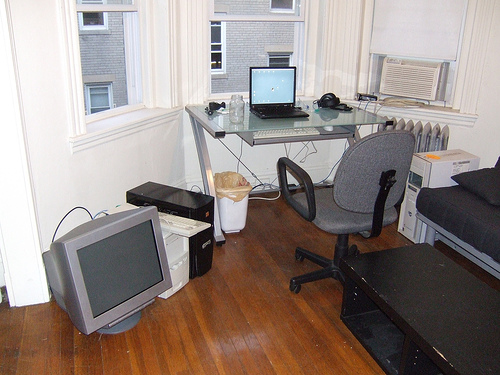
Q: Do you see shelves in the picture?
A: No, there are no shelves.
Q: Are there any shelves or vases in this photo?
A: No, there are no shelves or vases.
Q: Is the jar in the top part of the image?
A: Yes, the jar is in the top of the image.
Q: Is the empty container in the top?
A: Yes, the jar is in the top of the image.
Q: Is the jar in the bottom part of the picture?
A: No, the jar is in the top of the image.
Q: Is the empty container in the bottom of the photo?
A: No, the jar is in the top of the image.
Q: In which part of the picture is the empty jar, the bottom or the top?
A: The jar is in the top of the image.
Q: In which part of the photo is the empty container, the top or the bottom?
A: The jar is in the top of the image.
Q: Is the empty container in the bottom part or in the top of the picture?
A: The jar is in the top of the image.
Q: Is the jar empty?
A: Yes, the jar is empty.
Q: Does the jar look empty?
A: Yes, the jar is empty.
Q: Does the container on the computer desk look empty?
A: Yes, the jar is empty.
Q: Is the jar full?
A: No, the jar is empty.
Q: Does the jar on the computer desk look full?
A: No, the jar is empty.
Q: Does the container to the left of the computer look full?
A: No, the jar is empty.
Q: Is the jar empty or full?
A: The jar is empty.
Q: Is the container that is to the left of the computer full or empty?
A: The jar is empty.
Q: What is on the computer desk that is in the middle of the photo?
A: The jar is on the computer desk.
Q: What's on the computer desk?
A: The jar is on the computer desk.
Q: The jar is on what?
A: The jar is on the computer desk.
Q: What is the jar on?
A: The jar is on the computer desk.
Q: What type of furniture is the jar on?
A: The jar is on the computer desk.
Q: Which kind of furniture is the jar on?
A: The jar is on the computer desk.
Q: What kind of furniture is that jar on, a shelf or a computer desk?
A: The jar is on a computer desk.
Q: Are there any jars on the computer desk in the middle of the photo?
A: Yes, there is a jar on the computer desk.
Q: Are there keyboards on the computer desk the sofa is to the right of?
A: No, there is a jar on the computer desk.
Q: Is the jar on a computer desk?
A: Yes, the jar is on a computer desk.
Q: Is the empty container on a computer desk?
A: Yes, the jar is on a computer desk.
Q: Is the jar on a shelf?
A: No, the jar is on a computer desk.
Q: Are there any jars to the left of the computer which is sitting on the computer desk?
A: Yes, there is a jar to the left of the computer.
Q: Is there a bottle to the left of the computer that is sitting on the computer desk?
A: No, there is a jar to the left of the computer.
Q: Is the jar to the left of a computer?
A: Yes, the jar is to the left of a computer.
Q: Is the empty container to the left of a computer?
A: Yes, the jar is to the left of a computer.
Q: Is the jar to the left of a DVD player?
A: No, the jar is to the left of a computer.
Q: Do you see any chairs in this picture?
A: Yes, there is a chair.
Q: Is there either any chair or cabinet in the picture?
A: Yes, there is a chair.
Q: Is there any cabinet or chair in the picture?
A: Yes, there is a chair.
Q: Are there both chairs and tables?
A: Yes, there are both a chair and a table.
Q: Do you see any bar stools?
A: No, there are no bar stools.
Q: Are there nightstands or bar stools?
A: No, there are no bar stools or nightstands.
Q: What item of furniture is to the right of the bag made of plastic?
A: The piece of furniture is a chair.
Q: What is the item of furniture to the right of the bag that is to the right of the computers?
A: The piece of furniture is a chair.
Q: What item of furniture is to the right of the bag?
A: The piece of furniture is a chair.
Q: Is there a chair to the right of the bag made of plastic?
A: Yes, there is a chair to the right of the bag.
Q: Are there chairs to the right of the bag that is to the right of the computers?
A: Yes, there is a chair to the right of the bag.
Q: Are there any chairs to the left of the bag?
A: No, the chair is to the right of the bag.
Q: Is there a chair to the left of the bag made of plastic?
A: No, the chair is to the right of the bag.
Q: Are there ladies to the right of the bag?
A: No, there is a chair to the right of the bag.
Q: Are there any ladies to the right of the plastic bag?
A: No, there is a chair to the right of the bag.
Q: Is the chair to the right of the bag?
A: Yes, the chair is to the right of the bag.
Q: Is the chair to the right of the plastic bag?
A: Yes, the chair is to the right of the bag.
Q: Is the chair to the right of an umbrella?
A: No, the chair is to the right of the bag.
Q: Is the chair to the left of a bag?
A: No, the chair is to the right of a bag.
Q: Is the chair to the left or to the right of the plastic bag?
A: The chair is to the right of the bag.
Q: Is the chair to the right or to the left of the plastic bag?
A: The chair is to the right of the bag.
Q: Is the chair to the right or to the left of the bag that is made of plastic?
A: The chair is to the right of the bag.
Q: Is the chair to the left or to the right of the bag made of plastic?
A: The chair is to the right of the bag.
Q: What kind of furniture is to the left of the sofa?
A: The piece of furniture is a chair.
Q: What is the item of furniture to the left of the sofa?
A: The piece of furniture is a chair.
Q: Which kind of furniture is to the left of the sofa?
A: The piece of furniture is a chair.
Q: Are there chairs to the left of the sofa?
A: Yes, there is a chair to the left of the sofa.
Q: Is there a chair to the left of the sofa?
A: Yes, there is a chair to the left of the sofa.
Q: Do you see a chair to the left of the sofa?
A: Yes, there is a chair to the left of the sofa.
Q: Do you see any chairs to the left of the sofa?
A: Yes, there is a chair to the left of the sofa.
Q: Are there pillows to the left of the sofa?
A: No, there is a chair to the left of the sofa.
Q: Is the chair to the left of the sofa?
A: Yes, the chair is to the left of the sofa.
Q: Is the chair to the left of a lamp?
A: No, the chair is to the left of the sofa.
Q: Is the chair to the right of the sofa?
A: No, the chair is to the left of the sofa.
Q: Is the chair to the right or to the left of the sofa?
A: The chair is to the left of the sofa.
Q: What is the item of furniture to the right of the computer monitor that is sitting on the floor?
A: The piece of furniture is a chair.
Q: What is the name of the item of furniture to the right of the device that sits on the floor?
A: The piece of furniture is a chair.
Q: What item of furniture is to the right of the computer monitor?
A: The piece of furniture is a chair.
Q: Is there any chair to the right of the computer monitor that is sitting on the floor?
A: Yes, there is a chair to the right of the computer monitor.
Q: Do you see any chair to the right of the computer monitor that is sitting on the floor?
A: Yes, there is a chair to the right of the computer monitor.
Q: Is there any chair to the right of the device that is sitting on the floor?
A: Yes, there is a chair to the right of the computer monitor.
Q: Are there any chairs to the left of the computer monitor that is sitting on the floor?
A: No, the chair is to the right of the computer monitor.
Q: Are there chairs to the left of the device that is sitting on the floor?
A: No, the chair is to the right of the computer monitor.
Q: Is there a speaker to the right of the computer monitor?
A: No, there is a chair to the right of the computer monitor.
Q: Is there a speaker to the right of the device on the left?
A: No, there is a chair to the right of the computer monitor.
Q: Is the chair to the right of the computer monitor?
A: Yes, the chair is to the right of the computer monitor.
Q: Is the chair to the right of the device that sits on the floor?
A: Yes, the chair is to the right of the computer monitor.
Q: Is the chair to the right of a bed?
A: No, the chair is to the right of the computer monitor.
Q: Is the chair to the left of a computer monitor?
A: No, the chair is to the right of a computer monitor.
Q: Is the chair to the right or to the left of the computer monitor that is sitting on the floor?
A: The chair is to the right of the computer monitor.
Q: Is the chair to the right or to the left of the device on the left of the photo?
A: The chair is to the right of the computer monitor.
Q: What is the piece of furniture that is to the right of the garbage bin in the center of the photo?
A: The piece of furniture is a chair.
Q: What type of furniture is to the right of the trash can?
A: The piece of furniture is a chair.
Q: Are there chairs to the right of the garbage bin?
A: Yes, there is a chair to the right of the garbage bin.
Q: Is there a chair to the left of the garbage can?
A: No, the chair is to the right of the garbage can.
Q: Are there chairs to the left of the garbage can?
A: No, the chair is to the right of the garbage can.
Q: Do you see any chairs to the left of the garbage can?
A: No, the chair is to the right of the garbage can.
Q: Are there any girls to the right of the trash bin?
A: No, there is a chair to the right of the trash bin.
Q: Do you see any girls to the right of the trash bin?
A: No, there is a chair to the right of the trash bin.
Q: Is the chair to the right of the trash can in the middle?
A: Yes, the chair is to the right of the trashcan.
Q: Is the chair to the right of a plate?
A: No, the chair is to the right of the trashcan.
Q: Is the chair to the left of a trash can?
A: No, the chair is to the right of a trash can.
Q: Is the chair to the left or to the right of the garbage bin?
A: The chair is to the right of the garbage bin.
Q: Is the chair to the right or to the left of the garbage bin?
A: The chair is to the right of the garbage bin.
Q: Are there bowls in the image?
A: No, there are no bowls.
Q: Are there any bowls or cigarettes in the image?
A: No, there are no bowls or cigarettes.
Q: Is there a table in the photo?
A: Yes, there is a table.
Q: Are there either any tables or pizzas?
A: Yes, there is a table.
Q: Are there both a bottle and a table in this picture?
A: No, there is a table but no bottles.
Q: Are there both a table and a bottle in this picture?
A: No, there is a table but no bottles.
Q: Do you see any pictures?
A: No, there are no pictures.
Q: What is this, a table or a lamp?
A: This is a table.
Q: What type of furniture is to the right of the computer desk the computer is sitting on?
A: The piece of furniture is a table.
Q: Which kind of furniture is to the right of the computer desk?
A: The piece of furniture is a table.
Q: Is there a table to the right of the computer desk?
A: Yes, there is a table to the right of the computer desk.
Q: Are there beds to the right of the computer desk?
A: No, there is a table to the right of the computer desk.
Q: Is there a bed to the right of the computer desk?
A: No, there is a table to the right of the computer desk.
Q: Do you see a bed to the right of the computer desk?
A: No, there is a table to the right of the computer desk.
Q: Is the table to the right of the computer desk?
A: Yes, the table is to the right of the computer desk.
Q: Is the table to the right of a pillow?
A: No, the table is to the right of the computer desk.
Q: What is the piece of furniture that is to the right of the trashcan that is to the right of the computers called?
A: The piece of furniture is a table.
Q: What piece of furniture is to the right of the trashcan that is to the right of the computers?
A: The piece of furniture is a table.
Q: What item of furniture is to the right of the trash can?
A: The piece of furniture is a table.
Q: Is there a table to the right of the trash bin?
A: Yes, there is a table to the right of the trash bin.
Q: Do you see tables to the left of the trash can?
A: No, the table is to the right of the trash can.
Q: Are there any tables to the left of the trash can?
A: No, the table is to the right of the trash can.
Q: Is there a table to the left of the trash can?
A: No, the table is to the right of the trash can.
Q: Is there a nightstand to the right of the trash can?
A: No, there is a table to the right of the trash can.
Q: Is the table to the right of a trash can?
A: Yes, the table is to the right of a trash can.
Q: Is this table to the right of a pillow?
A: No, the table is to the right of a trash can.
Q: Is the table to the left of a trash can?
A: No, the table is to the right of a trash can.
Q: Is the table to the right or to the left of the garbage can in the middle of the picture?
A: The table is to the right of the trash can.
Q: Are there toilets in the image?
A: No, there are no toilets.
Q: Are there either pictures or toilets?
A: No, there are no toilets or pictures.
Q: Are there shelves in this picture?
A: No, there are no shelves.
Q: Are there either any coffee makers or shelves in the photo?
A: No, there are no shelves or coffee makers.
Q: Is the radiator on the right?
A: Yes, the radiator is on the right of the image.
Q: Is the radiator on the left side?
A: No, the radiator is on the right of the image.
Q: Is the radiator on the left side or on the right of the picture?
A: The radiator is on the right of the image.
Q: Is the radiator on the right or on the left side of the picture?
A: The radiator is on the right of the image.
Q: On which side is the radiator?
A: The radiator is on the right of the image.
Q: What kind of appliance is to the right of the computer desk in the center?
A: The appliance is a radiator.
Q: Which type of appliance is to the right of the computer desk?
A: The appliance is a radiator.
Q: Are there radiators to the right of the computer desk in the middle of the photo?
A: Yes, there is a radiator to the right of the computer desk.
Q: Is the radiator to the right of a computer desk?
A: Yes, the radiator is to the right of a computer desk.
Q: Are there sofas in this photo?
A: Yes, there is a sofa.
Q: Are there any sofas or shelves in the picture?
A: Yes, there is a sofa.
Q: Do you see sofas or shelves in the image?
A: Yes, there is a sofa.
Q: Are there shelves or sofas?
A: Yes, there is a sofa.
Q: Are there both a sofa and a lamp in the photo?
A: No, there is a sofa but no lamps.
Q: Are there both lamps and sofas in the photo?
A: No, there is a sofa but no lamps.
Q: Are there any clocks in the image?
A: No, there are no clocks.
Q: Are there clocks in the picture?
A: No, there are no clocks.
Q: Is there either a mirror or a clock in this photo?
A: No, there are no clocks or mirrors.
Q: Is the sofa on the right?
A: Yes, the sofa is on the right of the image.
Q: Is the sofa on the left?
A: No, the sofa is on the right of the image.